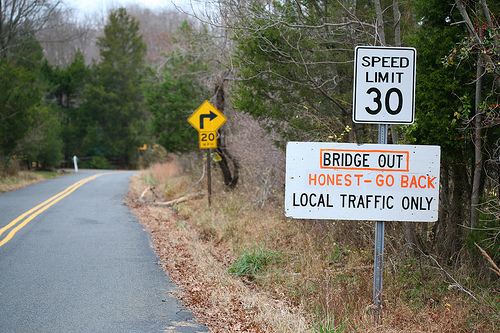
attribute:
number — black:
[198, 132, 208, 144]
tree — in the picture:
[156, 39, 256, 194]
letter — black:
[395, 154, 414, 173]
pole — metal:
[355, 124, 405, 311]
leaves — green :
[238, 23, 331, 102]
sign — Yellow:
[179, 88, 247, 161]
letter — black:
[360, 52, 372, 69]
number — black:
[364, 86, 406, 120]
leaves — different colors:
[439, 26, 499, 123]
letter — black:
[361, 55, 369, 66]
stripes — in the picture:
[11, 175, 96, 267]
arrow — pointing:
[199, 110, 218, 130]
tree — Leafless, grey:
[34, 5, 183, 59]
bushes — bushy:
[163, 149, 475, 326]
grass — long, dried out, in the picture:
[133, 160, 497, 332]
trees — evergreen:
[81, 24, 204, 159]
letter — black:
[391, 50, 423, 77]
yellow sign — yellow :
[182, 94, 234, 155]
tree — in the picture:
[67, 2, 160, 167]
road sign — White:
[351, 44, 416, 124]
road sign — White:
[284, 140, 441, 221]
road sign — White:
[186, 97, 227, 149]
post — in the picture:
[198, 99, 220, 198]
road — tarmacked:
[54, 220, 111, 309]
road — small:
[22, 182, 96, 244]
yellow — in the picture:
[186, 99, 231, 154]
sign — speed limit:
[311, 35, 444, 142]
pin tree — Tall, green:
[62, 1, 162, 178]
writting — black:
[359, 57, 409, 114]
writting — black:
[292, 152, 437, 211]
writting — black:
[200, 110, 217, 147]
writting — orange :
[309, 148, 435, 188]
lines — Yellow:
[0, 167, 139, 244]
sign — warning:
[282, 140, 441, 223]